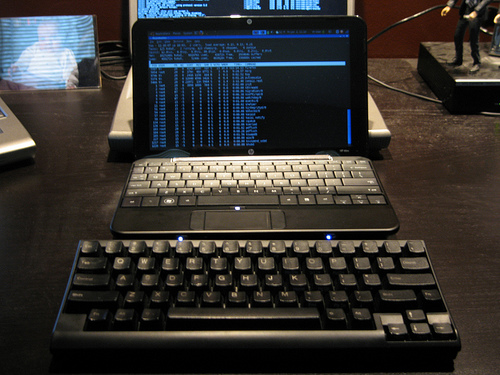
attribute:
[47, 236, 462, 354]
keyboard — black, detatched, sitting, behind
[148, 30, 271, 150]
writing — black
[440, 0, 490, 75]
figure — statue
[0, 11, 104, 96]
photo — sitting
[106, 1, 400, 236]
laptops — open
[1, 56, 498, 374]
table — brown, black, solid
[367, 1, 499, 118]
cord — connected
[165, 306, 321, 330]
spacebar — black, detatched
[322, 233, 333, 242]
light — blue, small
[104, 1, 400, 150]
laptop — behind, sitting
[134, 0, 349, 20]
screen — behind, lighted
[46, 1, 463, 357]
computers — sitting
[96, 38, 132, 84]
cables — attatched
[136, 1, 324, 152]
display — blue, lighted